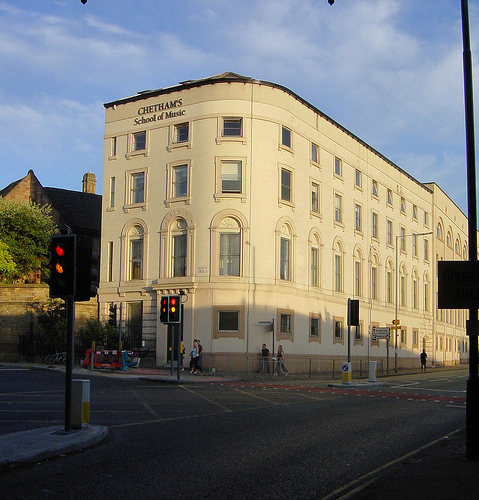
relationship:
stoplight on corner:
[156, 295, 183, 324] [133, 370, 234, 385]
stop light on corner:
[42, 232, 101, 328] [133, 370, 234, 385]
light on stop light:
[52, 261, 64, 274] [47, 233, 77, 296]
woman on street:
[274, 344, 289, 378] [3, 364, 473, 495]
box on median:
[342, 363, 350, 382] [253, 370, 462, 423]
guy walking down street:
[420, 347, 427, 373] [407, 370, 459, 425]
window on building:
[162, 213, 198, 280] [95, 72, 477, 376]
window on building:
[215, 153, 247, 199] [95, 72, 477, 376]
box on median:
[68, 376, 84, 431] [0, 419, 111, 470]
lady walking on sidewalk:
[189, 343, 197, 370] [54, 356, 279, 387]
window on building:
[218, 310, 239, 331] [95, 72, 477, 376]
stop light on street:
[30, 186, 129, 329] [8, 370, 345, 498]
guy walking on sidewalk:
[420, 347, 428, 373] [195, 360, 473, 381]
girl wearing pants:
[273, 344, 290, 377] [274, 355, 287, 371]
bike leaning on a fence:
[40, 351, 74, 368] [2, 330, 101, 369]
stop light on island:
[42, 232, 101, 328] [0, 416, 112, 469]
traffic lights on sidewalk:
[157, 291, 187, 378] [2, 351, 470, 384]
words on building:
[129, 99, 194, 129] [95, 71, 454, 289]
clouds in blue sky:
[2, 0, 477, 220] [3, 2, 475, 199]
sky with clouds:
[0, 2, 474, 192] [353, 11, 478, 129]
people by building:
[179, 338, 202, 374] [95, 72, 477, 376]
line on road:
[312, 415, 460, 498] [5, 364, 476, 495]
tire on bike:
[46, 354, 58, 363] [43, 350, 70, 365]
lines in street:
[102, 359, 377, 441] [3, 364, 473, 495]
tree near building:
[1, 195, 66, 290] [0, 168, 99, 364]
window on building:
[220, 113, 246, 138] [109, 69, 474, 337]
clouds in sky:
[2, 0, 477, 220] [3, 2, 468, 218]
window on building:
[217, 219, 256, 277] [95, 72, 477, 376]